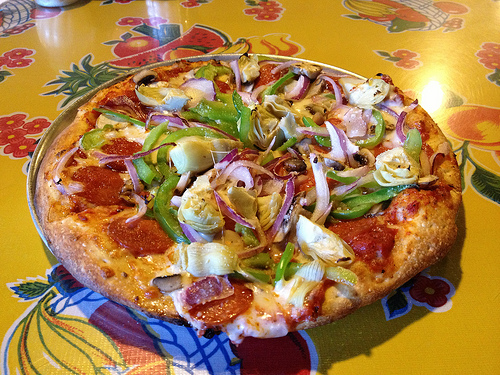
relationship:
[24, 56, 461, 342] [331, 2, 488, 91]
pizza pie sitting on colorful tablecloth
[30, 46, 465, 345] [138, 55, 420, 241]
pizza topped with onions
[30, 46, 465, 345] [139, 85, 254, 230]
pizza topped with peppers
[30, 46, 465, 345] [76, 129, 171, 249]
pizza topped with pepperoni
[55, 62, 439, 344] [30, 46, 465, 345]
cheese on pizza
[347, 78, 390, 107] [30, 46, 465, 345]
mushroom on pizza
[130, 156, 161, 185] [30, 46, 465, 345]
pepper on pizza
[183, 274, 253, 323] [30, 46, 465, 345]
slice pepperoni on pizza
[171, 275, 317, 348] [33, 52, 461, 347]
cheese on top of pizza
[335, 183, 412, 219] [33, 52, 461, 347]
pepper on top of pizza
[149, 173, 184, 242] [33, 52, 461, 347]
pepper on top of pizza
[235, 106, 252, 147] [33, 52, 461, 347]
pepper on top of pizza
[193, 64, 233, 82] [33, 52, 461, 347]
pepper on top of pizza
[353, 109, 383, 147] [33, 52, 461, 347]
pepper on top of pizza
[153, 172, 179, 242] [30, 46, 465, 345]
green pepper on pizza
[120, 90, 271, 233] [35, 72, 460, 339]
green pepper on pizza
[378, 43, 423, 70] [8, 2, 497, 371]
flower painted on table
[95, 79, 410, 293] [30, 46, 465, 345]
toppings on pizza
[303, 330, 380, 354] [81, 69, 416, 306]
shadow under pizza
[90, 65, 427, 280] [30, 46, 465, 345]
peppers on pizza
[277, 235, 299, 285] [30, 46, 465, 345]
pepper on pizza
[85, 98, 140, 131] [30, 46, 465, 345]
green pepper on pizza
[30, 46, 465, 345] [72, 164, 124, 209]
pizza with pepperoni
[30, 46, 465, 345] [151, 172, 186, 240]
pizza with artichoke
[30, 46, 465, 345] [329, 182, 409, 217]
pizza with artichoke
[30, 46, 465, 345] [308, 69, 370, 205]
pizza with red onions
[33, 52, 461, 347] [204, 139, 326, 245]
pizza with onions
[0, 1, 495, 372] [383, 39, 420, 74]
tablecloth with flower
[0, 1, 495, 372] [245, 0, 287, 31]
tablecloth with flower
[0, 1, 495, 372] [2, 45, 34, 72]
tablecloth with flower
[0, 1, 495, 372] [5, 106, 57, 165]
tablecloth with flower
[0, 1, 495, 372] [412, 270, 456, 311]
tablecloth with flower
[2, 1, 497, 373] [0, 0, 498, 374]
fruit decorates yellow tablecloth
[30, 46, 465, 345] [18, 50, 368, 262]
pizza on pan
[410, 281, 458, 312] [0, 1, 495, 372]
flower on tablecloth